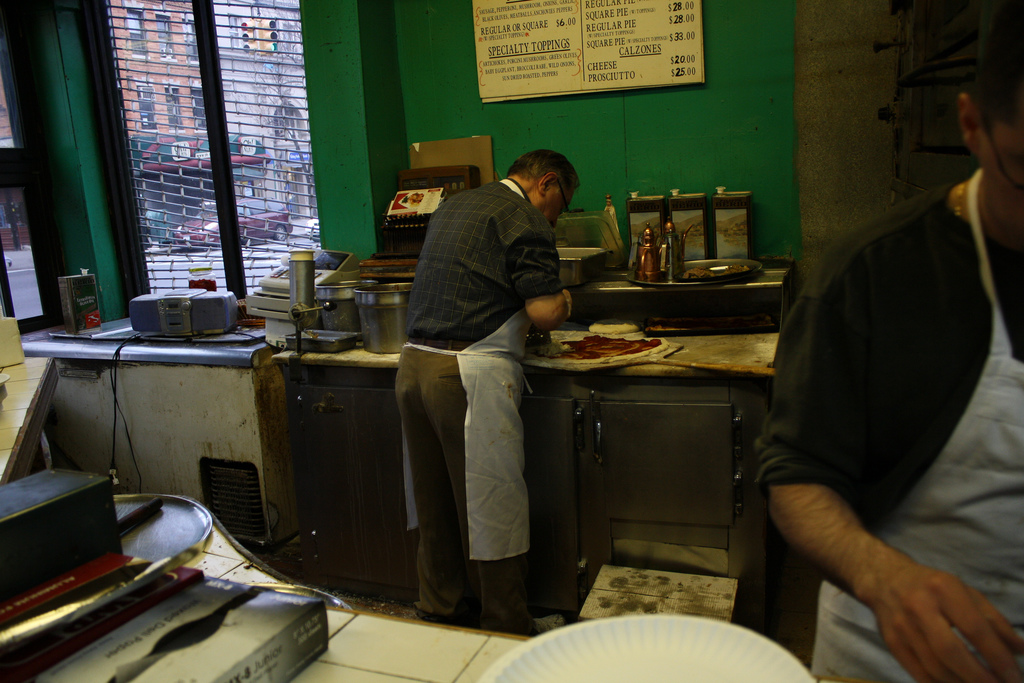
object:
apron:
[809, 167, 1015, 680]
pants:
[394, 342, 534, 630]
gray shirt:
[402, 172, 578, 355]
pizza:
[540, 324, 675, 363]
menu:
[458, 0, 718, 110]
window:
[103, 1, 317, 318]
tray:
[621, 231, 763, 286]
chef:
[388, 144, 582, 636]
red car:
[132, 142, 301, 253]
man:
[380, 140, 591, 637]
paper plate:
[474, 608, 828, 679]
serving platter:
[616, 250, 776, 290]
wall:
[619, 113, 795, 175]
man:
[729, 17, 1024, 679]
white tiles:
[316, 601, 483, 682]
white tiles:
[585, 556, 737, 613]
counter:
[651, 320, 777, 376]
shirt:
[385, 179, 565, 354]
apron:
[444, 316, 542, 564]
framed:
[72, 6, 129, 261]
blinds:
[217, 2, 317, 251]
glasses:
[540, 193, 573, 219]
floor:
[327, 628, 466, 682]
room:
[3, 5, 1023, 682]